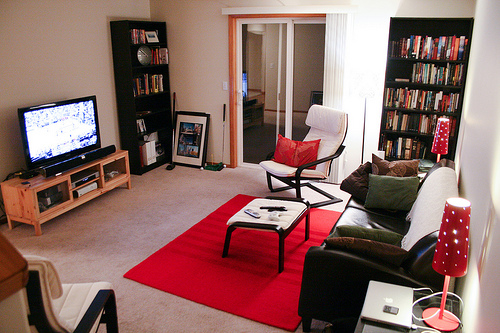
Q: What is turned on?
A: TV screen.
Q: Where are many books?
A: On shelves.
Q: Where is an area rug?
A: On the floor.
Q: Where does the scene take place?
A: In a living room.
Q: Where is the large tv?
A: On a rectangular stand.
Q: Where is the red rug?
A: In the middle of the floor.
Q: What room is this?
A: Living room.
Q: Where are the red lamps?
A: On the end tables.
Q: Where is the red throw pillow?
A: On the white chair.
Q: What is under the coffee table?
A: Red rug.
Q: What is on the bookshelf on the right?
A: Books.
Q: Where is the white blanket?
A: On the back of the couch.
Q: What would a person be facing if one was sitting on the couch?
A: The television.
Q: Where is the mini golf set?
A: Near the far wall on the left.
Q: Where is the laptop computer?
A: On one of the end tables.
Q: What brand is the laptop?
A: Apple.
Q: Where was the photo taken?
A: In livingroom.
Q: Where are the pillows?
A: On couch.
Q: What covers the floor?
A: Red rug.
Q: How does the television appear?
A: Operating.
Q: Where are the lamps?
A: Side tables.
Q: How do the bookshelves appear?
A: Full.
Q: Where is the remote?
A: Coffee table.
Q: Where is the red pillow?
A: On chair.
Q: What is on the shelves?
A: Books.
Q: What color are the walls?
A: White.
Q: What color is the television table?
A: Brown.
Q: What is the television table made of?
A: Wood.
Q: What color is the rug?
A: Red.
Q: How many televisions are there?
A: One.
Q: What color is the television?
A: Black.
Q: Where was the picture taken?
A: In a living room.